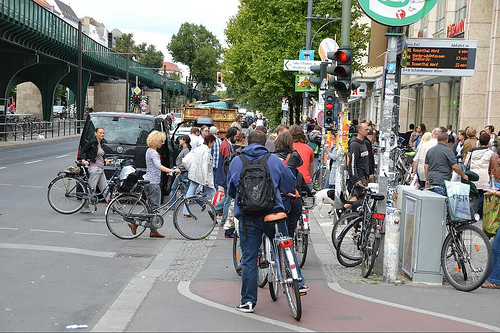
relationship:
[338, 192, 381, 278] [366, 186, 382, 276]
bike on a rack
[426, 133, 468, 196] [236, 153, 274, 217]
man has a backpack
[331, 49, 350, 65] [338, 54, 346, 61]
traffic light showing red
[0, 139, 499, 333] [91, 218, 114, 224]
street has a spot